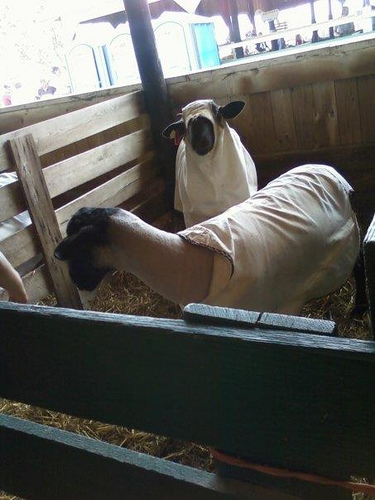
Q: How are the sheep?
A: Sheared.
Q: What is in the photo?
A: Sheep.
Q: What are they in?
A: Cage.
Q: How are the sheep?
A: Standing.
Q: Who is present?
A: Nobody.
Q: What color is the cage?
A: Brown.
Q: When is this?
A: Daytime.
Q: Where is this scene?
A: At a barn.